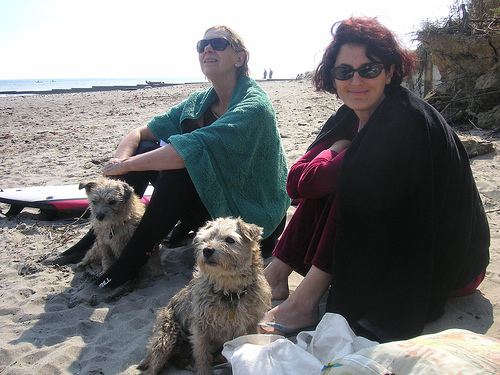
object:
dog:
[169, 221, 269, 341]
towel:
[250, 330, 380, 366]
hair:
[334, 31, 400, 59]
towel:
[214, 103, 289, 202]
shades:
[324, 64, 397, 79]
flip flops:
[260, 314, 324, 337]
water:
[10, 81, 138, 94]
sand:
[31, 96, 154, 135]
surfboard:
[3, 177, 92, 213]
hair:
[226, 25, 251, 54]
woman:
[174, 22, 251, 219]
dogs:
[58, 181, 279, 321]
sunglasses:
[186, 41, 240, 57]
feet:
[49, 252, 126, 300]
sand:
[21, 243, 147, 354]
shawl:
[210, 82, 283, 203]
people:
[264, 63, 283, 86]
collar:
[213, 287, 258, 301]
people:
[25, 75, 63, 89]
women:
[106, 57, 482, 259]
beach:
[27, 74, 485, 304]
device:
[22, 184, 117, 215]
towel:
[358, 113, 452, 215]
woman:
[303, 34, 460, 258]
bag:
[251, 336, 399, 372]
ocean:
[6, 41, 183, 84]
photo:
[31, 13, 475, 370]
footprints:
[42, 119, 83, 141]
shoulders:
[227, 88, 262, 139]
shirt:
[285, 153, 346, 208]